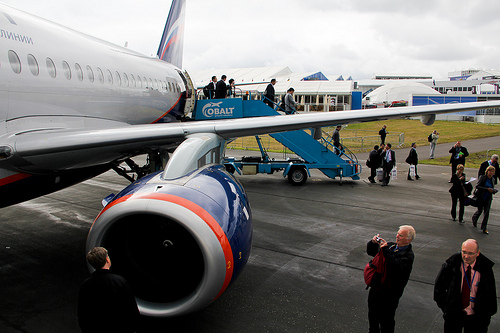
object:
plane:
[4, 10, 496, 319]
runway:
[3, 136, 498, 329]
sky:
[0, 1, 499, 81]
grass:
[214, 99, 499, 152]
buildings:
[200, 62, 499, 127]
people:
[360, 222, 414, 331]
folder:
[454, 153, 465, 159]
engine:
[81, 164, 253, 317]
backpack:
[362, 251, 389, 290]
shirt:
[456, 263, 484, 315]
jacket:
[430, 253, 499, 321]